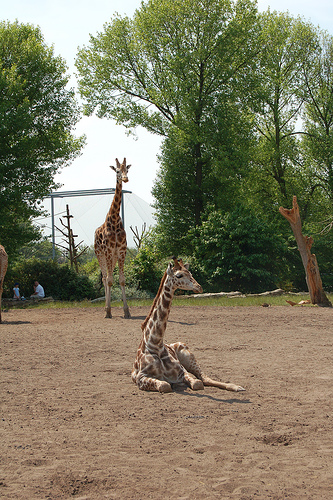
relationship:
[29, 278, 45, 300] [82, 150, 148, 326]
man watching giraffe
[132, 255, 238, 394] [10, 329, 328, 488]
giraffe sitting on dirt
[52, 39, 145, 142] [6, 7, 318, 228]
clouds in sky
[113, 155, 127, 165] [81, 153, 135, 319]
ossicles on giraffe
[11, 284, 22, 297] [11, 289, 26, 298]
girl wearing shirt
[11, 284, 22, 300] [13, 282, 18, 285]
girl wearing a hat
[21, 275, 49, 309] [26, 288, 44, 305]
man wearing pants